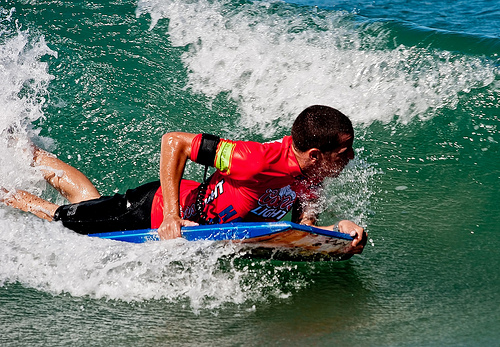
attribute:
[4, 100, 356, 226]
man — surfing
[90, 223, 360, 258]
surfboard — blue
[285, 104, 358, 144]
hair — dark, short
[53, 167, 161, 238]
shorts — black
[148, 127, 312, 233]
shirt — red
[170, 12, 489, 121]
wave — white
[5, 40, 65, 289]
water — splashing